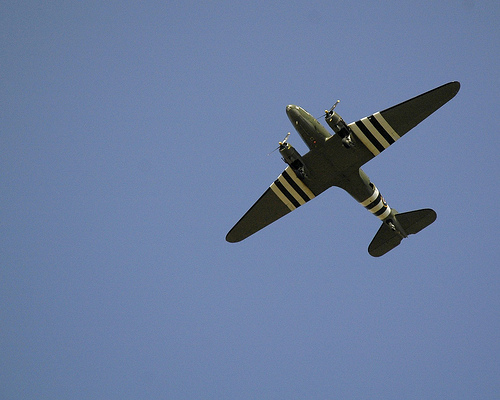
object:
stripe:
[346, 110, 401, 159]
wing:
[344, 79, 462, 167]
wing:
[225, 165, 331, 245]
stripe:
[268, 165, 314, 213]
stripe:
[358, 186, 389, 222]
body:
[345, 166, 395, 224]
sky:
[0, 2, 499, 399]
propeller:
[267, 130, 294, 157]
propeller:
[314, 99, 346, 125]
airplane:
[223, 81, 463, 259]